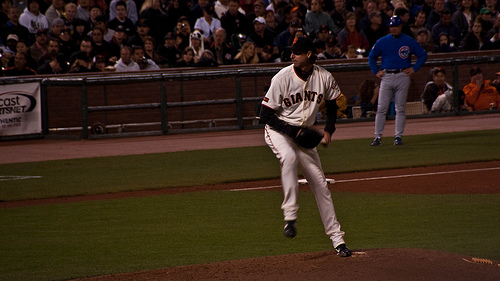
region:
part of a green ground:
[178, 210, 221, 257]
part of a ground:
[354, 246, 383, 276]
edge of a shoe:
[330, 244, 351, 263]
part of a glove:
[290, 123, 322, 163]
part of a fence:
[175, 97, 200, 122]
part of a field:
[186, 220, 229, 263]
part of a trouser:
[277, 168, 314, 224]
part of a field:
[184, 200, 223, 243]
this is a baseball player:
[249, 32, 358, 268]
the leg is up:
[277, 150, 312, 230]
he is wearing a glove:
[298, 123, 322, 145]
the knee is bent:
[281, 152, 298, 168]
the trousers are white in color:
[281, 154, 318, 199]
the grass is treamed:
[129, 199, 243, 259]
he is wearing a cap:
[290, 34, 311, 50]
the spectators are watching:
[125, 7, 212, 69]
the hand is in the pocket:
[400, 49, 430, 77]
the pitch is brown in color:
[400, 256, 422, 279]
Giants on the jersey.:
[278, 79, 334, 113]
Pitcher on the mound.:
[259, 35, 369, 261]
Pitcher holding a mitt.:
[291, 117, 328, 155]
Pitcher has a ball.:
[311, 122, 336, 152]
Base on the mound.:
[328, 242, 388, 270]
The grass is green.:
[84, 212, 194, 252]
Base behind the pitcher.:
[285, 162, 337, 197]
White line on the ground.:
[358, 163, 425, 188]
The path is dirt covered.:
[421, 167, 498, 193]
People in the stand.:
[32, 10, 372, 52]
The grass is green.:
[74, 207, 202, 249]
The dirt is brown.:
[415, 179, 487, 189]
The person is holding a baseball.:
[310, 131, 338, 154]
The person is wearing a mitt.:
[278, 115, 328, 159]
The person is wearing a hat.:
[278, 27, 325, 62]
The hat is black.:
[276, 30, 321, 64]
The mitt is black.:
[283, 117, 329, 158]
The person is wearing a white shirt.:
[244, 59, 346, 139]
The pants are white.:
[255, 112, 360, 259]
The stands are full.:
[2, 0, 499, 69]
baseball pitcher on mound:
[254, 26, 357, 266]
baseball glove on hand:
[283, 119, 328, 152]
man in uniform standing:
[355, 11, 433, 153]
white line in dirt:
[389, 161, 484, 183]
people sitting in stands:
[83, 6, 269, 61]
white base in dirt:
[285, 171, 338, 193]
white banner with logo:
[1, 73, 48, 141]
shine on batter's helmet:
[378, 11, 414, 34]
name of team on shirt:
[270, 86, 325, 112]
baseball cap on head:
[277, 27, 319, 63]